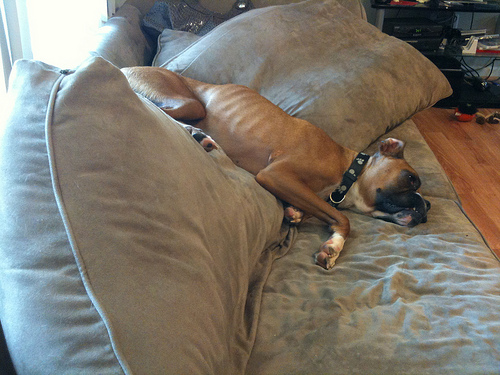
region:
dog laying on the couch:
[107, 55, 487, 350]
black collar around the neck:
[314, 140, 374, 211]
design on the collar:
[354, 157, 365, 166]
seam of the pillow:
[37, 75, 161, 374]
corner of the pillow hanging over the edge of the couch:
[384, 32, 469, 134]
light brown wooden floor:
[401, 95, 496, 245]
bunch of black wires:
[461, 54, 498, 81]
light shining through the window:
[28, 6, 108, 78]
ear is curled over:
[375, 135, 403, 163]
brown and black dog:
[128, 42, 453, 271]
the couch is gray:
[124, 211, 204, 305]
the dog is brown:
[126, 46, 443, 273]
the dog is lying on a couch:
[136, 39, 441, 269]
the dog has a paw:
[309, 234, 344, 276]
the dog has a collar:
[338, 149, 364, 185]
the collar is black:
[339, 144, 374, 194]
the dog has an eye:
[393, 162, 427, 194]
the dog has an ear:
[360, 129, 418, 156]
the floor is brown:
[456, 143, 491, 196]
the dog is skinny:
[113, 49, 448, 259]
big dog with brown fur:
[54, 48, 454, 304]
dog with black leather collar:
[208, 78, 455, 324]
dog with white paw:
[245, 176, 362, 299]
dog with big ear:
[328, 113, 433, 261]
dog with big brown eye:
[296, 116, 471, 256]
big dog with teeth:
[279, 134, 451, 261]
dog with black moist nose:
[323, 145, 448, 279]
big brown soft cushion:
[135, 3, 452, 215]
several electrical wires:
[440, 40, 499, 112]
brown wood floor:
[416, 129, 498, 209]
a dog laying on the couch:
[107, 50, 430, 276]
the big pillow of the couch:
[10, 15, 446, 372]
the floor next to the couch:
[410, 97, 495, 232]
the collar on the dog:
[326, 142, 371, 209]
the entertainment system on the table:
[377, 3, 487, 84]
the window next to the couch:
[0, 7, 38, 84]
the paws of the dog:
[269, 197, 346, 273]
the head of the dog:
[358, 134, 435, 243]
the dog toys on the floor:
[450, 99, 497, 125]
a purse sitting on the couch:
[138, 0, 240, 42]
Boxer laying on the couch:
[92, 49, 450, 269]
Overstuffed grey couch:
[3, 2, 498, 372]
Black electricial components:
[372, 0, 464, 57]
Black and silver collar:
[320, 138, 377, 213]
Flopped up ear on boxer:
[354, 125, 416, 170]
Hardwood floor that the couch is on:
[410, 118, 496, 265]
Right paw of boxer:
[308, 221, 366, 292]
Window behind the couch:
[0, 0, 112, 102]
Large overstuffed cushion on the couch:
[4, 1, 475, 370]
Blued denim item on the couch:
[135, 3, 270, 52]